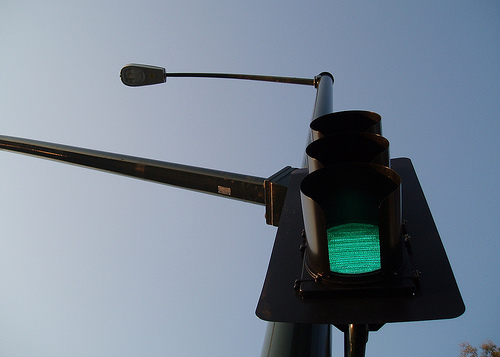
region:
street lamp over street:
[105, 40, 321, 80]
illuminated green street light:
[318, 205, 382, 283]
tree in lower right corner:
[445, 323, 487, 353]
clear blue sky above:
[101, 213, 222, 284]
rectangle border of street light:
[253, 170, 448, 328]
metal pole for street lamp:
[302, 60, 331, 295]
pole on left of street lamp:
[28, 95, 262, 225]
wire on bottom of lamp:
[339, 328, 371, 343]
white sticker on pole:
[204, 170, 239, 205]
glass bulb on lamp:
[114, 69, 141, 82]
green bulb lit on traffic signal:
[306, 177, 407, 312]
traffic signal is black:
[263, 259, 285, 314]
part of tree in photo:
[455, 330, 485, 350]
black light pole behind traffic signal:
[256, 329, 291, 352]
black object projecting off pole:
[146, 161, 213, 198]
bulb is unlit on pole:
[125, 61, 133, 73]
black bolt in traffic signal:
[270, 279, 341, 324]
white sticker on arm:
[204, 158, 234, 207]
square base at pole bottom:
[252, 153, 282, 262]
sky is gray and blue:
[216, 236, 273, 290]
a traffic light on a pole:
[235, 98, 461, 353]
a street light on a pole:
[87, 51, 344, 105]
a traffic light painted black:
[242, 103, 443, 346]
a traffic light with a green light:
[263, 86, 444, 333]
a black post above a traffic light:
[0, 123, 388, 205]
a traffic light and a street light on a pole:
[115, 28, 402, 283]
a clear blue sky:
[154, 12, 453, 47]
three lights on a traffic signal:
[291, 96, 399, 278]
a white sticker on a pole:
[209, 179, 251, 202]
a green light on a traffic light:
[291, 166, 425, 283]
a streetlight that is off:
[118, 53, 165, 90]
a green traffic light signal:
[297, 173, 410, 283]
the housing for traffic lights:
[280, 108, 453, 325]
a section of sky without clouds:
[221, 19, 334, 59]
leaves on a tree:
[455, 334, 494, 355]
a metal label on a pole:
[214, 185, 232, 196]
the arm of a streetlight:
[157, 64, 322, 94]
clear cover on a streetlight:
[122, 66, 145, 88]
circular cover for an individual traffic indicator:
[297, 159, 414, 278]